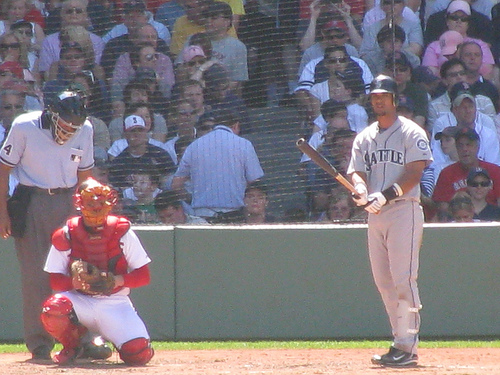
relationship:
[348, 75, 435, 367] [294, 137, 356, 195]
batter holding bat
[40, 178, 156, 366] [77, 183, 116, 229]
catcher wearing a facemask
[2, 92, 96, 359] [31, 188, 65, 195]
umpire wearing a belt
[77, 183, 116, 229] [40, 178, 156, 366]
facemask on catcher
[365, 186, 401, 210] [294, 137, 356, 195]
glove holding bat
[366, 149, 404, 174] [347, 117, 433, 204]
writing on jersey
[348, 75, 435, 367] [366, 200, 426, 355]
batter wearing pants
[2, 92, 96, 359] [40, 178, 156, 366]
umpire behind catcher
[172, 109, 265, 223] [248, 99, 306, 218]
man walking up stairs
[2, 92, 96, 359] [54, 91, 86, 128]
umpire wearing a helmet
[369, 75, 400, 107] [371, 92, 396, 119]
helmet on head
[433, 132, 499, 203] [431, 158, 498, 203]
man wearing a shirt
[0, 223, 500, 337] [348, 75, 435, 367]
wall behind batter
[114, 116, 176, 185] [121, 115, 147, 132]
man wearing a hat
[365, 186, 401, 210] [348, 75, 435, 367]
glove in front of batter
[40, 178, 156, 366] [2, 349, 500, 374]
catcher kneeling in dirt